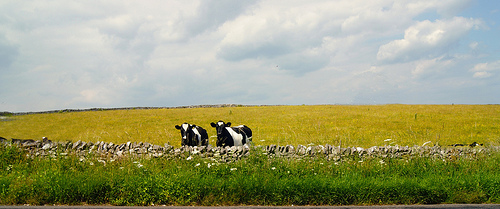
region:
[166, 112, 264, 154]
Two cows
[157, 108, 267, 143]
The cows are looking at the camera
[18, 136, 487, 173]
A long wall made of rock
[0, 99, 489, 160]
The cows are behind the rock wall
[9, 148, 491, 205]
Patch of tall grass in front of the wall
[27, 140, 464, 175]
There are white weeds in the grass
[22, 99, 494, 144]
A large field of grass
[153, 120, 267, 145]
The cows are standing on grass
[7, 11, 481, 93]
Tons of white clouds in the sky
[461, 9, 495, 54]
Blue sky peaking through the clouds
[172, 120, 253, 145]
two cows standing in field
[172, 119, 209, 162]
one cow behind low stone wall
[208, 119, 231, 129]
two black cow ears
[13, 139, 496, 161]
one low sunlit rock wall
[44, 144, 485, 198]
greenery in front of stone wall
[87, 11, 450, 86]
white puffy clouds in blue sky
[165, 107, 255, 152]
two adult sunlit cows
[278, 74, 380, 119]
yellow grassy field under blue sky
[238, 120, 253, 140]
one black and white cow behind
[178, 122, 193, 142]
one black and white cow head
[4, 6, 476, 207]
a large serene cow field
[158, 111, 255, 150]
two chill looking cows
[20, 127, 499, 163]
a rock wall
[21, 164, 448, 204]
dark green grass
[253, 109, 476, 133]
yellow green grass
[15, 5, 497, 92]
cloudy blue sky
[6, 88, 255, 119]
green trees on the horizon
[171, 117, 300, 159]
two black and white cows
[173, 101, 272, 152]
Milk machines contemplating the word "Moo" for all eternity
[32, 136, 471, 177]
A row of rocks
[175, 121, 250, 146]
two black and white cows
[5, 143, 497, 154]
a stacked stone fence in front of the cows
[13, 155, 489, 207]
tall green grass with white flowers in front of cows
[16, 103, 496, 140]
large yellow grass field behind cows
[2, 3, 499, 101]
gray cloudy sky above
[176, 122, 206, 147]
the left cow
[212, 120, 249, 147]
cow on the right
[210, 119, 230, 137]
the right cow's head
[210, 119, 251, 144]
the black and white cow on the right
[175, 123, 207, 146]
the smaller black and white cow on the left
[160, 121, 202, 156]
cow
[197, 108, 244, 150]
cow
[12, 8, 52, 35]
white clouds in blue sky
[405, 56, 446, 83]
white clouds in blue sky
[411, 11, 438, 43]
white clouds in blue sky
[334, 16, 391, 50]
white clouds in blue sky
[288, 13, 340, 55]
white clouds in blue sky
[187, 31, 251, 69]
white clouds in blue sky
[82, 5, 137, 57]
white clouds in blue sky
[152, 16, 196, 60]
white clouds in blue sky